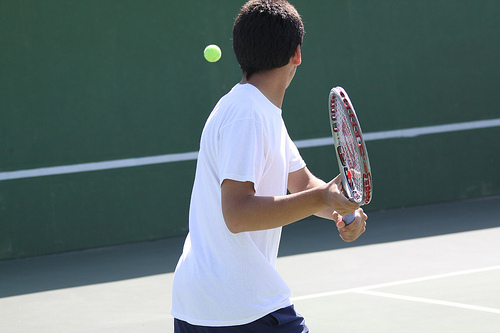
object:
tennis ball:
[201, 40, 226, 64]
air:
[18, 29, 145, 105]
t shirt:
[160, 84, 311, 326]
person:
[166, 4, 377, 332]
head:
[228, 0, 310, 81]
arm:
[212, 104, 354, 236]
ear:
[294, 41, 307, 70]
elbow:
[225, 192, 255, 238]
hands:
[316, 168, 367, 214]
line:
[2, 140, 189, 184]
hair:
[230, 0, 311, 72]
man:
[166, 0, 370, 331]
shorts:
[169, 305, 314, 330]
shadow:
[4, 194, 500, 296]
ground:
[2, 205, 499, 333]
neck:
[235, 69, 288, 108]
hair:
[245, 72, 252, 80]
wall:
[5, 0, 167, 110]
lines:
[355, 261, 500, 330]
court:
[2, 197, 499, 324]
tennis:
[110, 4, 433, 327]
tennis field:
[3, 184, 500, 327]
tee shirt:
[169, 78, 316, 328]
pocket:
[264, 312, 307, 329]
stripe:
[386, 115, 489, 150]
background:
[5, 5, 499, 253]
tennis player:
[167, 4, 371, 331]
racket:
[327, 83, 374, 228]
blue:
[174, 308, 317, 332]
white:
[187, 250, 270, 296]